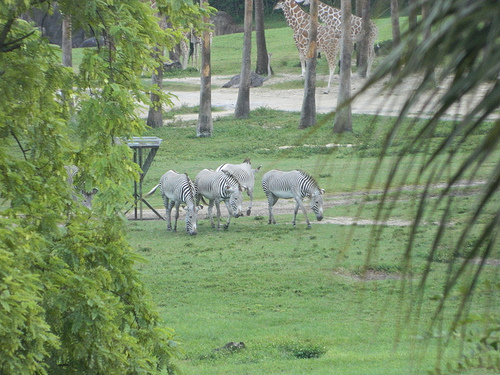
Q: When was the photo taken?
A: Daytime.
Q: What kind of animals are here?
A: Zebras and giraffes.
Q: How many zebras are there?
A: Four.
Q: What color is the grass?
A: Green.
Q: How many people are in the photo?
A: None.